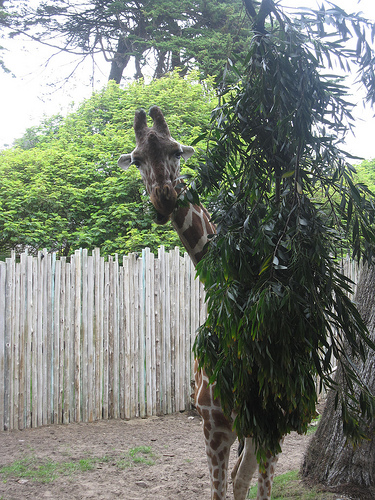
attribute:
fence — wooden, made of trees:
[0, 243, 205, 430]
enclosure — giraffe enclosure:
[1, 247, 374, 499]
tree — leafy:
[0, 63, 374, 261]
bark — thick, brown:
[294, 236, 371, 498]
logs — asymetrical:
[4, 235, 204, 440]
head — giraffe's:
[110, 101, 205, 227]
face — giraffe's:
[112, 106, 201, 230]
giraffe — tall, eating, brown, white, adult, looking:
[113, 103, 292, 498]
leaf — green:
[326, 34, 349, 46]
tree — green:
[103, 15, 176, 84]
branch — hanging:
[183, 28, 373, 461]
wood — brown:
[73, 247, 85, 425]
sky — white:
[0, 1, 373, 163]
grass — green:
[21, 448, 144, 475]